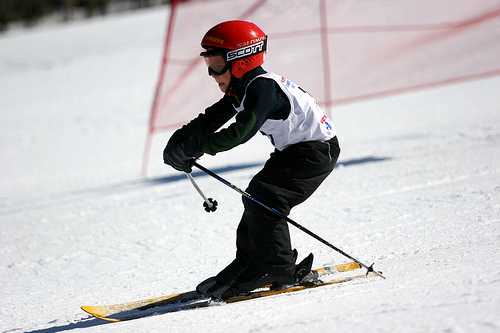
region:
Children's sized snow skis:
[78, 258, 384, 323]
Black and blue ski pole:
[189, 161, 387, 283]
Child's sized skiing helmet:
[201, 19, 267, 74]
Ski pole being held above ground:
[173, 158, 217, 213]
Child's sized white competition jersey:
[229, 71, 339, 152]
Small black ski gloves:
[161, 133, 199, 170]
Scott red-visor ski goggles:
[200, 39, 265, 74]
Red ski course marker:
[311, 0, 498, 122]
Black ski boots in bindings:
[201, 245, 301, 290]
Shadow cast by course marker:
[336, 153, 393, 165]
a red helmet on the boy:
[198, 19, 269, 79]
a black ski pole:
[186, 155, 395, 282]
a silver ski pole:
[181, 166, 221, 218]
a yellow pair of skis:
[76, 255, 392, 324]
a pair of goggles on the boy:
[196, 46, 235, 78]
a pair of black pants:
[219, 135, 340, 271]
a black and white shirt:
[183, 67, 338, 185]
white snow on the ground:
[2, 0, 497, 331]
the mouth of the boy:
[214, 78, 228, 88]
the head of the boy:
[194, 20, 273, 95]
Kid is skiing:
[133, 9, 356, 306]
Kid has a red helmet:
[159, 9, 356, 328]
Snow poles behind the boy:
[179, 160, 398, 302]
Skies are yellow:
[51, 251, 387, 324]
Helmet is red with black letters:
[151, 13, 352, 322]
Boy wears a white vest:
[144, 7, 358, 305]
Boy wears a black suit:
[136, 13, 356, 311]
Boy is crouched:
[143, 13, 356, 315]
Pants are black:
[220, 137, 365, 268]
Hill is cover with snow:
[11, 11, 498, 320]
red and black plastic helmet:
[201, 22, 271, 82]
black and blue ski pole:
[182, 156, 384, 280]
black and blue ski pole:
[180, 164, 225, 219]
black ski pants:
[217, 144, 365, 268]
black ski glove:
[161, 130, 184, 160]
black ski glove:
[170, 137, 204, 173]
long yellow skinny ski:
[70, 252, 364, 312]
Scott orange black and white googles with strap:
[197, 34, 266, 74]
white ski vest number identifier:
[227, 73, 342, 147]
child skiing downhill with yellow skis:
[79, 17, 381, 322]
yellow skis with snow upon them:
[79, 258, 384, 323]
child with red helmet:
[162, 20, 339, 298]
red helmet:
[200, 18, 267, 78]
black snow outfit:
[162, 65, 342, 299]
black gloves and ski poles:
[159, 125, 388, 279]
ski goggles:
[200, 46, 230, 76]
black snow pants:
[233, 132, 340, 283]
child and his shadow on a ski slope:
[19, 18, 384, 331]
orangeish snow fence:
[138, 2, 498, 180]